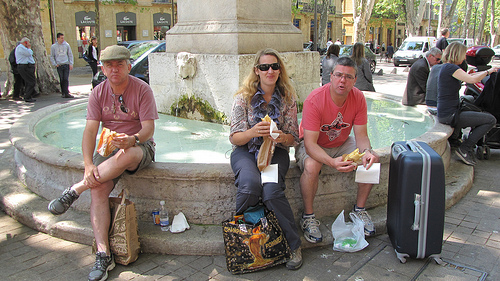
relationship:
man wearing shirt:
[47, 44, 159, 280] [79, 73, 159, 145]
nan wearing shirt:
[294, 55, 382, 246] [297, 81, 368, 151]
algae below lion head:
[169, 93, 230, 125] [177, 49, 198, 83]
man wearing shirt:
[49, 31, 78, 101] [49, 41, 74, 69]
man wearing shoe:
[47, 44, 159, 280] [46, 184, 84, 216]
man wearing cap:
[47, 44, 159, 280] [98, 44, 133, 63]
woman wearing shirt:
[435, 39, 499, 165] [434, 60, 465, 122]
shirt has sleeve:
[79, 73, 159, 145] [84, 85, 104, 122]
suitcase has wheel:
[386, 136, 448, 269] [431, 255, 448, 268]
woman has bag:
[227, 47, 303, 271] [222, 203, 294, 277]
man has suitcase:
[294, 53, 381, 244] [386, 136, 448, 269]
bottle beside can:
[157, 197, 172, 234] [151, 206, 161, 229]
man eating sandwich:
[294, 53, 381, 244] [342, 148, 371, 169]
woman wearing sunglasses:
[227, 47, 303, 271] [256, 62, 281, 72]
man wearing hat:
[47, 44, 159, 280] [98, 44, 133, 63]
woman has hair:
[435, 39, 499, 165] [440, 40, 468, 65]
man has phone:
[14, 37, 39, 104] [23, 40, 30, 47]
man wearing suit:
[400, 39, 445, 107] [401, 57, 429, 107]